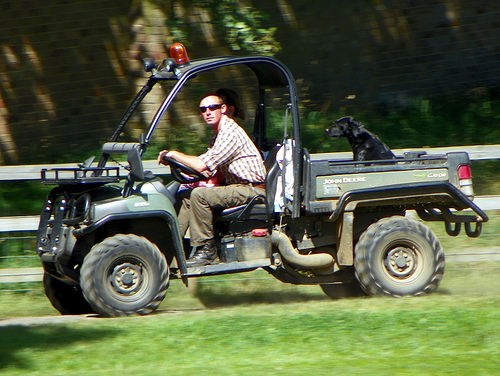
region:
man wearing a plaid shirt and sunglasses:
[155, 92, 266, 264]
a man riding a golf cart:
[40, 41, 465, 318]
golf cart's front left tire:
[77, 235, 171, 317]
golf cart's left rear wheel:
[352, 216, 447, 297]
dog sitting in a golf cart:
[322, 115, 397, 160]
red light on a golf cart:
[165, 36, 187, 66]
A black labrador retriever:
[325, 114, 396, 165]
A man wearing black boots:
[156, 94, 266, 268]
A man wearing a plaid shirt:
[156, 94, 266, 264]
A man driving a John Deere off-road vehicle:
[37, 42, 487, 314]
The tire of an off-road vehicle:
[80, 231, 170, 314]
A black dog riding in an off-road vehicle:
[37, 42, 487, 315]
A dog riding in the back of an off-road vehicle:
[37, 43, 489, 314]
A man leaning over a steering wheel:
[155, 94, 270, 264]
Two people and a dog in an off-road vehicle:
[38, 42, 490, 314]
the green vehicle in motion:
[37, 41, 488, 315]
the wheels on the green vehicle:
[38, 42, 489, 316]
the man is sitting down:
[158, 93, 266, 265]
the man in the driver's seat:
[157, 95, 267, 263]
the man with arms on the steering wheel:
[158, 94, 268, 266]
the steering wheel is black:
[163, 156, 208, 183]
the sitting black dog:
[325, 115, 399, 165]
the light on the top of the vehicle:
[35, 42, 487, 315]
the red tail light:
[458, 162, 471, 179]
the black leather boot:
[185, 239, 221, 268]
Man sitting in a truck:
[156, 95, 270, 260]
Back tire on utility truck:
[351, 216, 451, 297]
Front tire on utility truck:
[72, 235, 172, 310]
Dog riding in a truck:
[322, 115, 401, 167]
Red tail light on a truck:
[457, 163, 471, 179]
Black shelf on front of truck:
[42, 164, 122, 180]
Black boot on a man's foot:
[190, 240, 219, 268]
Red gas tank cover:
[247, 225, 270, 238]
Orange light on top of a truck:
[164, 40, 196, 67]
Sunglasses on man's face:
[195, 101, 225, 110]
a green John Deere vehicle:
[39, 24, 484, 309]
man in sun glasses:
[161, 80, 302, 280]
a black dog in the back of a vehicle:
[310, 91, 475, 303]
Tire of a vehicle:
[347, 211, 454, 307]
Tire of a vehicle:
[78, 227, 173, 322]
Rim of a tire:
[108, 260, 148, 298]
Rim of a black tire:
[110, 259, 146, 293]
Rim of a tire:
[384, 245, 419, 277]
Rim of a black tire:
[383, 241, 420, 278]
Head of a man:
[197, 90, 228, 129]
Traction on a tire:
[359, 224, 382, 255]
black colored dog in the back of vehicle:
[313, 116, 408, 168]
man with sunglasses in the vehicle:
[158, 83, 272, 272]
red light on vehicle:
[163, 39, 190, 71]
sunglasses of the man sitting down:
[191, 98, 220, 113]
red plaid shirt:
[201, 114, 266, 186]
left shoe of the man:
[169, 239, 220, 269]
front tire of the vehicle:
[70, 233, 172, 316]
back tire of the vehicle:
[351, 221, 446, 298]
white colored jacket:
[266, 134, 306, 222]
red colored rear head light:
[452, 156, 474, 187]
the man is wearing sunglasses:
[200, 103, 222, 113]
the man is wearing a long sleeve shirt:
[195, 115, 265, 184]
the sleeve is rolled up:
[199, 125, 235, 169]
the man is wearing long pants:
[177, 178, 265, 250]